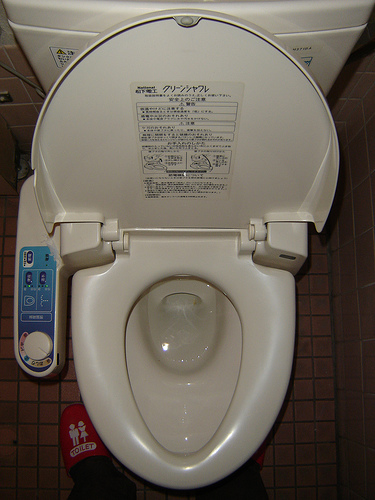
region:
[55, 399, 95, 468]
red cup on the floor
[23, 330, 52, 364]
dial on the arm of the toliet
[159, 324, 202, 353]
water in the toliet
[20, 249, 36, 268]
button on the arm of the toliet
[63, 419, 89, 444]
male and female on the cup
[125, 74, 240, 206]
instructions sticker on the back of toliet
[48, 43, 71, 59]
warning label on the toliet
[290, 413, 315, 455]
brown floor with black tiles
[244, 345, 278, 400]
seat of the toliet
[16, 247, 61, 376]
control panel on the arm of the toilet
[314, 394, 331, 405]
Small brown grout line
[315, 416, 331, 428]
Small brown grout line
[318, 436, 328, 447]
Small brown grout line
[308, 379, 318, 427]
Small brown grout line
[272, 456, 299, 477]
Small brown grout line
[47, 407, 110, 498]
Red slipper on floor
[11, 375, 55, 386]
Small brown grout line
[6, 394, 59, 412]
Small brown grout line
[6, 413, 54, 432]
Small brown grout line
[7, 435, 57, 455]
Small brown grout line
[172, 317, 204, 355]
water in the toilet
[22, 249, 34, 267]
button on the toilet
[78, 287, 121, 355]
seat of the toilet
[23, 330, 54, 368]
dial on the toilet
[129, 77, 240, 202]
directions sticker on the cover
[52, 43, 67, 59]
warning sticker on the toilet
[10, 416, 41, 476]
brown floor with black lines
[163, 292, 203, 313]
hole that the toilet paper flushes to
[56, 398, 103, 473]
cup on the floor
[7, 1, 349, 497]
toilet in a bathroom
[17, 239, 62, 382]
controls for a toilet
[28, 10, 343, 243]
lid on a toilet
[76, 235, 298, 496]
seat on a toilet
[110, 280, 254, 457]
bowl of a toilet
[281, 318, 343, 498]
tile on the floor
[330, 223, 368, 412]
tile on the wall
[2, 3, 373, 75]
tank of a toilet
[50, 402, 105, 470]
red shoe that says Toilet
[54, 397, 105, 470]
red and white shoe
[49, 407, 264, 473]
red and white slippers of person standing in front of toilet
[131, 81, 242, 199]
white sticker with black text on toilet lid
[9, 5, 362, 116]
tank of the white toilet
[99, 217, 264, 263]
hinges on the toilet lid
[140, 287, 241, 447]
bowl of white toilet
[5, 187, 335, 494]
brown flooring around toilet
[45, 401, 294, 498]
person standing in front of toilet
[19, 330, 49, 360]
control knob next to toilet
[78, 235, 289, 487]
seat of the white toilet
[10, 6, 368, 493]
white toilet with lid up